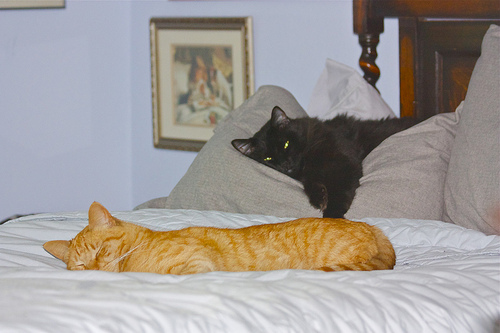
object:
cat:
[42, 199, 395, 274]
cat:
[230, 105, 424, 220]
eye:
[95, 245, 103, 256]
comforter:
[1, 209, 499, 332]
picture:
[149, 17, 254, 154]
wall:
[255, 2, 331, 86]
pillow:
[134, 84, 459, 221]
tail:
[319, 223, 397, 272]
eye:
[284, 140, 290, 149]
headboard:
[352, 1, 498, 117]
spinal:
[358, 31, 380, 86]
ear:
[88, 200, 113, 224]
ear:
[231, 138, 253, 157]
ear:
[271, 106, 287, 122]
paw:
[311, 184, 329, 210]